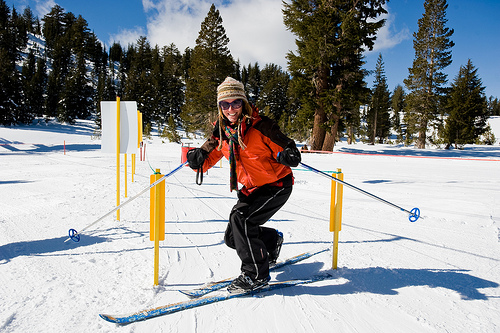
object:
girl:
[176, 69, 303, 296]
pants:
[217, 170, 294, 283]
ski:
[73, 272, 290, 329]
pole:
[299, 160, 487, 247]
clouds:
[231, 16, 275, 49]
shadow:
[281, 233, 495, 308]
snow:
[19, 158, 448, 297]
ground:
[14, 122, 492, 328]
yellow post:
[307, 160, 355, 272]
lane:
[168, 145, 323, 316]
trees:
[0, 0, 499, 152]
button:
[209, 74, 254, 107]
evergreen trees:
[1, 0, 498, 156]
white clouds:
[171, 14, 326, 61]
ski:
[179, 247, 329, 297]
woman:
[183, 76, 299, 293]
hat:
[215, 73, 254, 148]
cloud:
[108, 2, 410, 72]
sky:
[4, 0, 484, 91]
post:
[146, 172, 169, 279]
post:
[328, 169, 344, 273]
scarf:
[215, 117, 249, 188]